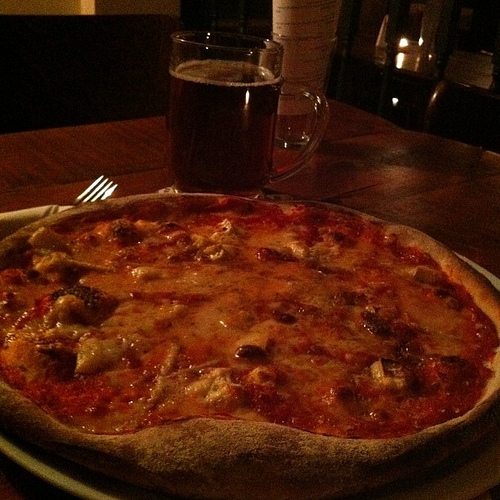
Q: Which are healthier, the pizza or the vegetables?
A: The vegetables are healthier than the pizza.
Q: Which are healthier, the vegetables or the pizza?
A: The vegetables are healthier than the pizza.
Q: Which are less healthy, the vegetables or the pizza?
A: The pizza are less healthy than the vegetables.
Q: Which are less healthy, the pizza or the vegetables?
A: The pizza are less healthy than the vegetables.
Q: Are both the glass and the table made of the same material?
A: No, the glass is made of glass and the table is made of wood.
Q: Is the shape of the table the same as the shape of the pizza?
A: No, the pizza is round and the table is square.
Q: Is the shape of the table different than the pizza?
A: Yes, the pizza is round and the table is square.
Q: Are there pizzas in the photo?
A: Yes, there is a pizza.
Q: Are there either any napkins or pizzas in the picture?
A: Yes, there is a pizza.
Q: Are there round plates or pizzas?
A: Yes, there is a round pizza.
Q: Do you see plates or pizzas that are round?
A: Yes, the pizza is round.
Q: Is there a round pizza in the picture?
A: Yes, there is a round pizza.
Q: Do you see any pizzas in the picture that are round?
A: Yes, there is a pizza that is round.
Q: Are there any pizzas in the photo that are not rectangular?
A: Yes, there is a round pizza.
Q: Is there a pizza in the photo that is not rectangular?
A: Yes, there is a round pizza.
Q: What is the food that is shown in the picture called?
A: The food is a pizza.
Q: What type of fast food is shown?
A: The fast food is a pizza.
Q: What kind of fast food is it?
A: The food is a pizza.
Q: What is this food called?
A: This is a pizza.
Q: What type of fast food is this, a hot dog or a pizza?
A: This is a pizza.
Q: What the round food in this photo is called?
A: The food is a pizza.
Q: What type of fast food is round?
A: The fast food is a pizza.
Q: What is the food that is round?
A: The food is a pizza.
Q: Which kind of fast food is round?
A: The fast food is a pizza.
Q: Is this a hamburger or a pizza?
A: This is a pizza.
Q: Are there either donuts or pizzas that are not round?
A: No, there is a pizza but it is round.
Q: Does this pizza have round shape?
A: Yes, the pizza is round.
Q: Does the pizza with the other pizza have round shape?
A: Yes, the pizza is round.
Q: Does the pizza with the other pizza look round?
A: Yes, the pizza is round.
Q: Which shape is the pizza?
A: The pizza is round.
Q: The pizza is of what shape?
A: The pizza is round.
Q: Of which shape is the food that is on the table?
A: The pizza is round.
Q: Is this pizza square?
A: No, the pizza is round.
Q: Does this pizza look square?
A: No, the pizza is round.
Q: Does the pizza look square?
A: No, the pizza is round.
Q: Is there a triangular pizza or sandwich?
A: No, there is a pizza but it is round.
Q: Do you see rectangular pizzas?
A: No, there is a pizza but it is round.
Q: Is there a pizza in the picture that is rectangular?
A: No, there is a pizza but it is round.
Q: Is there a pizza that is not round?
A: No, there is a pizza but it is round.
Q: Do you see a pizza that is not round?
A: No, there is a pizza but it is round.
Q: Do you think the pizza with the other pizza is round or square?
A: The pizza is round.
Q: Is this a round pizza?
A: Yes, this is a round pizza.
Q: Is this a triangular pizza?
A: No, this is a round pizza.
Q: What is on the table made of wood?
A: The pizza is on the table.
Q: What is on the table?
A: The pizza is on the table.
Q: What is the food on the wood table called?
A: The food is a pizza.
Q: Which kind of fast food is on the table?
A: The food is a pizza.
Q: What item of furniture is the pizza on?
A: The pizza is on the table.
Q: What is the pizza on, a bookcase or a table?
A: The pizza is on a table.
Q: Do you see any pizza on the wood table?
A: Yes, there is a pizza on the table.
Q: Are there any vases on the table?
A: No, there is a pizza on the table.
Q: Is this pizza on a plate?
A: No, the pizza is on the table.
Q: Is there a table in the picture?
A: Yes, there is a table.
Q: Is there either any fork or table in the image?
A: Yes, there is a table.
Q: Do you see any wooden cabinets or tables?
A: Yes, there is a wood table.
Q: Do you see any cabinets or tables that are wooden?
A: Yes, the table is wooden.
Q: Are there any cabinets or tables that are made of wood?
A: Yes, the table is made of wood.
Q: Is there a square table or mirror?
A: Yes, there is a square table.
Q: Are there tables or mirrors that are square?
A: Yes, the table is square.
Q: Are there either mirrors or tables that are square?
A: Yes, the table is square.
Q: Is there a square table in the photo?
A: Yes, there is a square table.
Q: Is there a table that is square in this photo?
A: Yes, there is a square table.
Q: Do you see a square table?
A: Yes, there is a square table.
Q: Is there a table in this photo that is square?
A: Yes, there is a table that is square.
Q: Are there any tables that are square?
A: Yes, there is a table that is square.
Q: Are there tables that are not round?
A: Yes, there is a square table.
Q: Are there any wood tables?
A: Yes, there is a wood table.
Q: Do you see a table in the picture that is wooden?
A: Yes, there is a table that is wooden.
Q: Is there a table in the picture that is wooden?
A: Yes, there is a table that is wooden.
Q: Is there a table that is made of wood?
A: Yes, there is a table that is made of wood.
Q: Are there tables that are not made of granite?
A: Yes, there is a table that is made of wood.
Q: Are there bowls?
A: No, there are no bowls.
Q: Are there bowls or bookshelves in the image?
A: No, there are no bowls or bookshelves.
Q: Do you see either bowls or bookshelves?
A: No, there are no bowls or bookshelves.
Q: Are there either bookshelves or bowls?
A: No, there are no bowls or bookshelves.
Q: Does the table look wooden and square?
A: Yes, the table is wooden and square.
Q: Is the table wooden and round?
A: No, the table is wooden but square.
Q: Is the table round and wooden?
A: No, the table is wooden but square.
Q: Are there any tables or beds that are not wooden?
A: No, there is a table but it is wooden.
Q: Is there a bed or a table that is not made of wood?
A: No, there is a table but it is made of wood.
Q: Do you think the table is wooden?
A: Yes, the table is wooden.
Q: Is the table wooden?
A: Yes, the table is wooden.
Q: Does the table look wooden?
A: Yes, the table is wooden.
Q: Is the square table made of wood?
A: Yes, the table is made of wood.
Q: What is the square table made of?
A: The table is made of wood.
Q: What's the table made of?
A: The table is made of wood.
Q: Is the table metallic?
A: No, the table is wooden.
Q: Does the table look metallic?
A: No, the table is wooden.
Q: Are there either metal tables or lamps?
A: No, there is a table but it is wooden.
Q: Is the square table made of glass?
A: No, the table is made of wood.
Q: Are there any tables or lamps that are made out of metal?
A: No, there is a table but it is made of wood.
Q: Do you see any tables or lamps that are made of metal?
A: No, there is a table but it is made of wood.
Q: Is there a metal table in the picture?
A: No, there is a table but it is made of wood.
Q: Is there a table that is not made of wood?
A: No, there is a table but it is made of wood.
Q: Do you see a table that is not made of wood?
A: No, there is a table but it is made of wood.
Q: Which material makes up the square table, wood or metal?
A: The table is made of wood.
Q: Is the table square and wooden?
A: Yes, the table is square and wooden.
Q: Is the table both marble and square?
A: No, the table is square but wooden.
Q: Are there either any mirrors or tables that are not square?
A: No, there is a table but it is square.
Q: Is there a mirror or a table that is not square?
A: No, there is a table but it is square.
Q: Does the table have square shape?
A: Yes, the table is square.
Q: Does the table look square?
A: Yes, the table is square.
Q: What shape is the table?
A: The table is square.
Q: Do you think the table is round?
A: No, the table is square.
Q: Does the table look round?
A: No, the table is square.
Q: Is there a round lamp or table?
A: No, there is a table but it is square.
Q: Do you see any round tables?
A: No, there is a table but it is square.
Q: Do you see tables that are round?
A: No, there is a table but it is square.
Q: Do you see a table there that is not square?
A: No, there is a table but it is square.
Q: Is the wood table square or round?
A: The table is square.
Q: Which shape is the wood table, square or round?
A: The table is square.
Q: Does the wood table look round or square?
A: The table is square.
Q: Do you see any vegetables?
A: Yes, there are vegetables.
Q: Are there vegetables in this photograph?
A: Yes, there are vegetables.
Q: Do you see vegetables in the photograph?
A: Yes, there are vegetables.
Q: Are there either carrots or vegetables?
A: Yes, there are vegetables.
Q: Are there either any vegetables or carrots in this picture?
A: Yes, there are vegetables.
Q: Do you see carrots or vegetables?
A: Yes, there are vegetables.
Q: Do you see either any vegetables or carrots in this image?
A: Yes, there are vegetables.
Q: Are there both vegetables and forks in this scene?
A: Yes, there are both vegetables and a fork.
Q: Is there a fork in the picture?
A: Yes, there is a fork.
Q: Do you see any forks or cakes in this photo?
A: Yes, there is a fork.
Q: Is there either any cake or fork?
A: Yes, there is a fork.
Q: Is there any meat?
A: No, there is no meat.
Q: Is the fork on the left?
A: Yes, the fork is on the left of the image.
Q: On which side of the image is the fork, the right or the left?
A: The fork is on the left of the image.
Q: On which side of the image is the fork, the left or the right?
A: The fork is on the left of the image.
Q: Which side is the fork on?
A: The fork is on the left of the image.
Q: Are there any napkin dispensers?
A: No, there are no napkin dispensers.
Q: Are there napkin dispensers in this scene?
A: No, there are no napkin dispensers.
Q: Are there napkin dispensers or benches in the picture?
A: No, there are no napkin dispensers or benches.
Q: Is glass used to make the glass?
A: Yes, the glass is made of glass.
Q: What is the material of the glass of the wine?
A: The glass is made of glass.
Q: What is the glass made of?
A: The glass is made of glass.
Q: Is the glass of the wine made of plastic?
A: No, the glass is made of glass.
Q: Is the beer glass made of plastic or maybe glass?
A: The glass is made of glass.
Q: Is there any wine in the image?
A: Yes, there is wine.